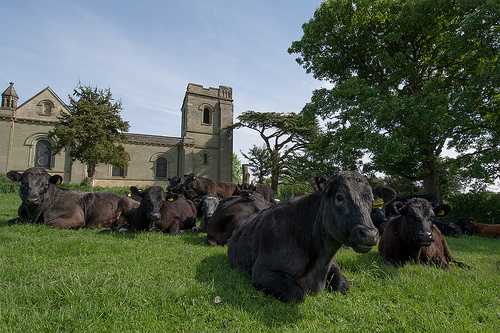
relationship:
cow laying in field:
[225, 160, 383, 303] [87, 222, 219, 289]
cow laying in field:
[211, 185, 267, 251] [87, 222, 219, 289]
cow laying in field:
[381, 194, 463, 280] [87, 222, 219, 289]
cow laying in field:
[119, 186, 198, 237] [87, 222, 219, 289]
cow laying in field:
[9, 152, 147, 243] [87, 222, 219, 289]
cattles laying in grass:
[6, 168, 500, 302] [0, 191, 497, 331]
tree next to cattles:
[215, 0, 499, 223] [6, 168, 500, 302]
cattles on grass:
[6, 145, 482, 302] [0, 190, 500, 331]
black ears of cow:
[312, 175, 327, 189] [225, 160, 383, 303]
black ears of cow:
[367, 182, 394, 199] [225, 160, 383, 303]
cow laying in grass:
[228, 171, 379, 303] [0, 191, 497, 331]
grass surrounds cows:
[6, 231, 497, 331] [1, 154, 481, 314]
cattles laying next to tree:
[6, 168, 500, 302] [293, 2, 498, 239]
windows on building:
[33, 135, 185, 185] [6, 60, 279, 213]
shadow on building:
[148, 134, 240, 199] [2, 66, 299, 233]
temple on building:
[2, 78, 17, 116] [1, 60, 241, 229]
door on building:
[19, 137, 58, 182] [0, 74, 240, 210]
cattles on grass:
[6, 168, 500, 302] [0, 191, 497, 331]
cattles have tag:
[6, 168, 500, 302] [167, 193, 175, 203]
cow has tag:
[228, 171, 379, 303] [370, 193, 384, 209]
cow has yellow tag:
[228, 171, 379, 303] [373, 198, 384, 207]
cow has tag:
[228, 171, 379, 303] [437, 206, 445, 218]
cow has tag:
[5, 167, 140, 229] [55, 176, 65, 186]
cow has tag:
[116, 178, 201, 237] [164, 195, 175, 204]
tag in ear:
[373, 195, 384, 206] [372, 182, 397, 212]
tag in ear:
[437, 206, 445, 218] [433, 202, 455, 219]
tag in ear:
[55, 176, 65, 186] [46, 172, 66, 186]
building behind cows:
[4, 60, 240, 209] [62, 182, 454, 284]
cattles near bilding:
[6, 168, 500, 302] [2, 80, 233, 196]